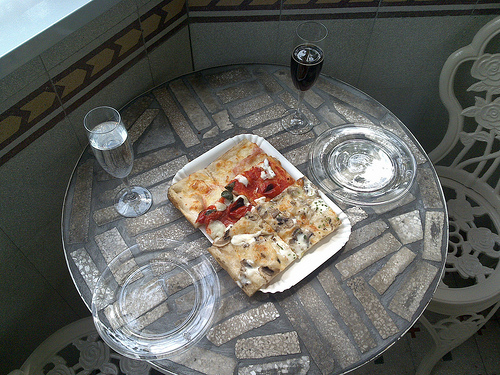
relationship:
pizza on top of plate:
[168, 140, 341, 297] [172, 134, 351, 294]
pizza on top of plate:
[254, 179, 341, 258] [172, 134, 351, 294]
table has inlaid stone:
[63, 64, 449, 375] [153, 87, 200, 148]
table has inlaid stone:
[63, 64, 449, 375] [336, 233, 403, 277]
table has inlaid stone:
[63, 64, 449, 375] [229, 95, 273, 119]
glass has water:
[86, 107, 153, 218] [90, 121, 134, 178]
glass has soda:
[282, 21, 328, 134] [291, 45, 323, 92]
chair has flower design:
[0, 316, 163, 374] [79, 344, 109, 369]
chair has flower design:
[421, 15, 498, 374] [450, 197, 494, 276]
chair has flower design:
[421, 15, 498, 374] [471, 52, 499, 130]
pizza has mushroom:
[208, 209, 296, 297] [232, 232, 264, 247]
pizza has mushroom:
[208, 209, 296, 297] [264, 267, 273, 276]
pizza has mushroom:
[208, 209, 296, 297] [215, 231, 232, 245]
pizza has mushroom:
[208, 209, 296, 297] [242, 260, 252, 268]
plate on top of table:
[172, 134, 351, 294] [63, 64, 449, 375]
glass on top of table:
[86, 107, 153, 218] [63, 64, 449, 375]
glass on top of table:
[282, 21, 328, 134] [63, 64, 449, 375]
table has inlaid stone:
[63, 64, 449, 375] [234, 332, 300, 357]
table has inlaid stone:
[63, 64, 449, 375] [389, 260, 439, 321]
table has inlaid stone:
[63, 64, 449, 375] [294, 282, 361, 369]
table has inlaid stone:
[63, 64, 449, 375] [317, 267, 379, 352]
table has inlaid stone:
[63, 64, 449, 375] [389, 211, 424, 245]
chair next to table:
[0, 316, 163, 374] [63, 64, 449, 375]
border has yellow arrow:
[1, 1, 499, 166] [55, 69, 87, 97]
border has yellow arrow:
[1, 1, 499, 166] [117, 28, 141, 56]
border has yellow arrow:
[1, 1, 499, 166] [22, 92, 59, 123]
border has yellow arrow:
[1, 1, 499, 166] [87, 46, 115, 78]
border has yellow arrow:
[1, 1, 499, 166] [142, 11, 161, 37]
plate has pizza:
[172, 134, 351, 294] [168, 140, 341, 297]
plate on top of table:
[308, 123, 417, 207] [63, 64, 449, 375]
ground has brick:
[348, 226, 498, 374] [408, 328, 485, 374]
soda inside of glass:
[291, 45, 323, 92] [282, 21, 328, 134]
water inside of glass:
[90, 121, 134, 178] [86, 107, 153, 218]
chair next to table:
[421, 15, 498, 374] [63, 64, 449, 375]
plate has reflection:
[308, 123, 417, 207] [319, 127, 408, 194]